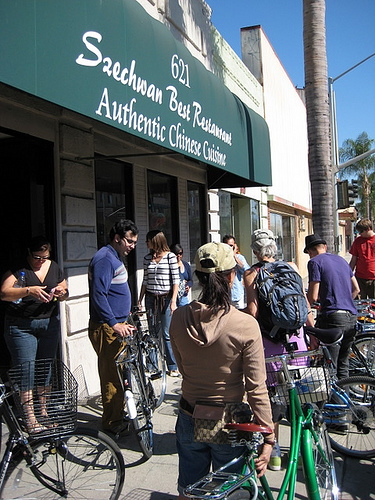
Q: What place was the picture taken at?
A: It was taken at the pavement.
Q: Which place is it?
A: It is a pavement.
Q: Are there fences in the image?
A: No, there are no fences.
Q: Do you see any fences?
A: No, there are no fences.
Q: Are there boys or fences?
A: No, there are no fences or boys.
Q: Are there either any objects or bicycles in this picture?
A: Yes, there is a bicycle.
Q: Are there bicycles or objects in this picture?
A: Yes, there is a bicycle.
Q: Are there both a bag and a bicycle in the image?
A: Yes, there are both a bicycle and a bag.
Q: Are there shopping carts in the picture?
A: No, there are no shopping carts.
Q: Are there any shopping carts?
A: No, there are no shopping carts.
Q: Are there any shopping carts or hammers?
A: No, there are no shopping carts or hammers.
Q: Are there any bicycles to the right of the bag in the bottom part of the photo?
A: Yes, there is a bicycle to the right of the bag.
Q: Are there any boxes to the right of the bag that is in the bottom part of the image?
A: No, there is a bicycle to the right of the bag.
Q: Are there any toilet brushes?
A: No, there are no toilet brushes.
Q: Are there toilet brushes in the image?
A: No, there are no toilet brushes.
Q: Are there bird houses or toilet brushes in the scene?
A: No, there are no toilet brushes or bird houses.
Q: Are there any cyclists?
A: Yes, there is a cyclist.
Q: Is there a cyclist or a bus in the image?
A: Yes, there is a cyclist.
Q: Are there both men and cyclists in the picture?
A: Yes, there are both a cyclist and a man.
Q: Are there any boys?
A: No, there are no boys.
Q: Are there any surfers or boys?
A: No, there are no boys or surfers.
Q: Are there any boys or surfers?
A: No, there are no boys or surfers.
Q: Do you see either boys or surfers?
A: No, there are no boys or surfers.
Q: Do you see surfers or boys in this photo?
A: No, there are no boys or surfers.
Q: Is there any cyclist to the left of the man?
A: Yes, there is a cyclist to the left of the man.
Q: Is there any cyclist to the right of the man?
A: No, the cyclist is to the left of the man.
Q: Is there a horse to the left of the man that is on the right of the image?
A: No, there is a cyclist to the left of the man.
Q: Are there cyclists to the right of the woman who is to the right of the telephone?
A: Yes, there is a cyclist to the right of the woman.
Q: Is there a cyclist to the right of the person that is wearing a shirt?
A: Yes, there is a cyclist to the right of the woman.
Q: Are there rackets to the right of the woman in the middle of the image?
A: No, there is a cyclist to the right of the woman.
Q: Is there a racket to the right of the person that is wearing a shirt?
A: No, there is a cyclist to the right of the woman.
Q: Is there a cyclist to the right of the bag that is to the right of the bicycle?
A: Yes, there is a cyclist to the right of the bag.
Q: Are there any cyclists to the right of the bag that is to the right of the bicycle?
A: Yes, there is a cyclist to the right of the bag.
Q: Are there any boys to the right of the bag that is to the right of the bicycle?
A: No, there is a cyclist to the right of the bag.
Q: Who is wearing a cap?
A: The cyclist is wearing a cap.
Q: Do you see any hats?
A: Yes, there is a hat.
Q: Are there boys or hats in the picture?
A: Yes, there is a hat.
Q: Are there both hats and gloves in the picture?
A: No, there is a hat but no gloves.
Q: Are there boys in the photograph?
A: No, there are no boys.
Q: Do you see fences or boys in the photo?
A: No, there are no boys or fences.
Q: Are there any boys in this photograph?
A: No, there are no boys.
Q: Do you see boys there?
A: No, there are no boys.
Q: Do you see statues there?
A: No, there are no statues.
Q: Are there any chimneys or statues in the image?
A: No, there are no statues or chimneys.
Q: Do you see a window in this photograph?
A: Yes, there is a window.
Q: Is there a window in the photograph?
A: Yes, there is a window.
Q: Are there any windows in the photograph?
A: Yes, there is a window.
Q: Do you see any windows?
A: Yes, there is a window.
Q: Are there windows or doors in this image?
A: Yes, there is a window.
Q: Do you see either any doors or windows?
A: Yes, there is a window.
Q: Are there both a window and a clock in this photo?
A: No, there is a window but no clocks.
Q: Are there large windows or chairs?
A: Yes, there is a large window.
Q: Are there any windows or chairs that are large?
A: Yes, the window is large.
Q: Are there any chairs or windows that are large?
A: Yes, the window is large.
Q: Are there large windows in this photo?
A: Yes, there is a large window.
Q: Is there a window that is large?
A: Yes, there is a window that is large.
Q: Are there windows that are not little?
A: Yes, there is a large window.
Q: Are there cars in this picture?
A: No, there are no cars.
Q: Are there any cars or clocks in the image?
A: No, there are no cars or clocks.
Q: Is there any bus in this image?
A: No, there are no buses.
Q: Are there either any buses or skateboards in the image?
A: No, there are no buses or skateboards.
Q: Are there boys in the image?
A: No, there are no boys.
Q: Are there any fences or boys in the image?
A: No, there are no boys or fences.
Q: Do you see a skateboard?
A: No, there are no skateboards.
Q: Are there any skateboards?
A: No, there are no skateboards.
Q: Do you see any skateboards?
A: No, there are no skateboards.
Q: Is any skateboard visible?
A: No, there are no skateboards.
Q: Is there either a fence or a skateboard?
A: No, there are no skateboards or fences.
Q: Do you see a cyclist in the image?
A: Yes, there is a cyclist.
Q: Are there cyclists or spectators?
A: Yes, there is a cyclist.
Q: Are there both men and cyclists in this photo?
A: Yes, there are both a cyclist and a man.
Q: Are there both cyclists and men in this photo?
A: Yes, there are both a cyclist and a man.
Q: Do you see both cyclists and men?
A: Yes, there are both a cyclist and a man.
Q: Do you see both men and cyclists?
A: Yes, there are both a cyclist and a man.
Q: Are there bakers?
A: No, there are no bakers.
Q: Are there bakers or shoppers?
A: No, there are no bakers or shoppers.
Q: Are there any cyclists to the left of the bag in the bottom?
A: Yes, there is a cyclist to the left of the bag.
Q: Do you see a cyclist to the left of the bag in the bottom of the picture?
A: Yes, there is a cyclist to the left of the bag.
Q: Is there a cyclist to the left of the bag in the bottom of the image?
A: Yes, there is a cyclist to the left of the bag.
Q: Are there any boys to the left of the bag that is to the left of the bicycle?
A: No, there is a cyclist to the left of the bag.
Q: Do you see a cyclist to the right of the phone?
A: Yes, there is a cyclist to the right of the phone.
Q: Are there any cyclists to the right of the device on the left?
A: Yes, there is a cyclist to the right of the phone.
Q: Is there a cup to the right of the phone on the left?
A: No, there is a cyclist to the right of the telephone.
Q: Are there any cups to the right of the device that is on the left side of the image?
A: No, there is a cyclist to the right of the telephone.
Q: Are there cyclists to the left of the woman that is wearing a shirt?
A: Yes, there is a cyclist to the left of the woman.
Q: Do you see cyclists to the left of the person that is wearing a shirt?
A: Yes, there is a cyclist to the left of the woman.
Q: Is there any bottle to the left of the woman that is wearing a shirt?
A: No, there is a cyclist to the left of the woman.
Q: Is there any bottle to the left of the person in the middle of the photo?
A: No, there is a cyclist to the left of the woman.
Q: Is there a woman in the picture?
A: Yes, there is a woman.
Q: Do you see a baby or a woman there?
A: Yes, there is a woman.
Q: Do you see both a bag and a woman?
A: Yes, there are both a woman and a bag.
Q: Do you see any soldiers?
A: No, there are no soldiers.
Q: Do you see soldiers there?
A: No, there are no soldiers.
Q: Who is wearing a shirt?
A: The woman is wearing a shirt.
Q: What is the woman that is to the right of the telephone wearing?
A: The woman is wearing a shirt.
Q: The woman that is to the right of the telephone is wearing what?
A: The woman is wearing a shirt.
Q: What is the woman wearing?
A: The woman is wearing a shirt.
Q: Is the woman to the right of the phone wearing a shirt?
A: Yes, the woman is wearing a shirt.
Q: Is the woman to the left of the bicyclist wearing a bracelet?
A: No, the woman is wearing a shirt.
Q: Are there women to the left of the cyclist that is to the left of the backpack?
A: Yes, there is a woman to the left of the bicyclist.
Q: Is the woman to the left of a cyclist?
A: Yes, the woman is to the left of a cyclist.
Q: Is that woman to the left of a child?
A: No, the woman is to the left of a cyclist.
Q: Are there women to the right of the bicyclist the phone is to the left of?
A: Yes, there is a woman to the right of the bicyclist.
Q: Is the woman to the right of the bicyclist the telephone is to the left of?
A: Yes, the woman is to the right of the cyclist.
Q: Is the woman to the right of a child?
A: No, the woman is to the right of the cyclist.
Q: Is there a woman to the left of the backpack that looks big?
A: Yes, there is a woman to the left of the backpack.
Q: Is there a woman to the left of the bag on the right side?
A: Yes, there is a woman to the left of the backpack.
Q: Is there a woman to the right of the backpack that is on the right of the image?
A: No, the woman is to the left of the backpack.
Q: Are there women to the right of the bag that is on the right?
A: No, the woman is to the left of the backpack.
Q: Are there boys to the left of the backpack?
A: No, there is a woman to the left of the backpack.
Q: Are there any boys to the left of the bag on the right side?
A: No, there is a woman to the left of the backpack.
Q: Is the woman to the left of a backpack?
A: Yes, the woman is to the left of a backpack.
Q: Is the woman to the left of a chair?
A: No, the woman is to the left of a backpack.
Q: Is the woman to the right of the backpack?
A: No, the woman is to the left of the backpack.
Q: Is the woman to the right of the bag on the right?
A: No, the woman is to the left of the backpack.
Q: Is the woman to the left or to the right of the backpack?
A: The woman is to the left of the backpack.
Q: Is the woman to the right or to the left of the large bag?
A: The woman is to the left of the backpack.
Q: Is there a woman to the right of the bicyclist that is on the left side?
A: Yes, there is a woman to the right of the bicyclist.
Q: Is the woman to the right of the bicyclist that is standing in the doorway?
A: Yes, the woman is to the right of the bicyclist.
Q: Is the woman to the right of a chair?
A: No, the woman is to the right of the bicyclist.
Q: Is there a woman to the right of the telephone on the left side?
A: Yes, there is a woman to the right of the telephone.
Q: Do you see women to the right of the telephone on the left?
A: Yes, there is a woman to the right of the telephone.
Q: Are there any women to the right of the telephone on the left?
A: Yes, there is a woman to the right of the telephone.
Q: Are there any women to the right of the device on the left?
A: Yes, there is a woman to the right of the telephone.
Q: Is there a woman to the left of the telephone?
A: No, the woman is to the right of the telephone.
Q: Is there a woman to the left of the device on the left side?
A: No, the woman is to the right of the telephone.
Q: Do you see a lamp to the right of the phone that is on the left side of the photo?
A: No, there is a woman to the right of the phone.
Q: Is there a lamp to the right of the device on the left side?
A: No, there is a woman to the right of the phone.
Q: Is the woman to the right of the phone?
A: Yes, the woman is to the right of the phone.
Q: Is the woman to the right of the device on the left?
A: Yes, the woman is to the right of the phone.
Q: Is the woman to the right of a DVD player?
A: No, the woman is to the right of the phone.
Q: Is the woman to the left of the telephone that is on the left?
A: No, the woman is to the right of the telephone.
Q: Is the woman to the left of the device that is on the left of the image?
A: No, the woman is to the right of the telephone.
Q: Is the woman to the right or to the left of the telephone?
A: The woman is to the right of the telephone.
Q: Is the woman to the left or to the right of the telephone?
A: The woman is to the right of the telephone.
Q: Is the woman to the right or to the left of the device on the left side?
A: The woman is to the right of the telephone.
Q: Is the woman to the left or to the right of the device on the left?
A: The woman is to the right of the telephone.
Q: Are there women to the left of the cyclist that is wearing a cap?
A: Yes, there is a woman to the left of the bicyclist.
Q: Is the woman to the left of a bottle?
A: No, the woman is to the left of a cyclist.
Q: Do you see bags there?
A: Yes, there is a bag.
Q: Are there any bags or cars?
A: Yes, there is a bag.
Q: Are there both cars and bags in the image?
A: No, there is a bag but no cars.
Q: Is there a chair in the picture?
A: No, there are no chairs.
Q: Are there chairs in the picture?
A: No, there are no chairs.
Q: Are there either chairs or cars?
A: No, there are no chairs or cars.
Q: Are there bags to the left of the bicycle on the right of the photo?
A: Yes, there is a bag to the left of the bicycle.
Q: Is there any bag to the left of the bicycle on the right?
A: Yes, there is a bag to the left of the bicycle.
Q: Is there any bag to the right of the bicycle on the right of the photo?
A: No, the bag is to the left of the bicycle.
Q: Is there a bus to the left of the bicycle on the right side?
A: No, there is a bag to the left of the bicycle.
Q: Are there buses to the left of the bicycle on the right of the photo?
A: No, there is a bag to the left of the bicycle.